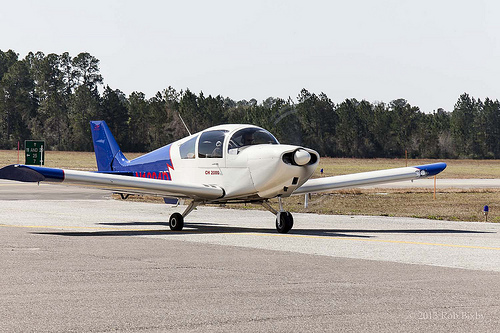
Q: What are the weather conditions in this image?
A: It is cloudy.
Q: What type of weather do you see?
A: It is cloudy.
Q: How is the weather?
A: It is cloudy.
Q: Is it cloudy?
A: Yes, it is cloudy.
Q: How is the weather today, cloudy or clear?
A: It is cloudy.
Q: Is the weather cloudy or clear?
A: It is cloudy.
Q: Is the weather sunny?
A: No, it is cloudy.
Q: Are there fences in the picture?
A: No, there are no fences.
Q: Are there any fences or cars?
A: No, there are no fences or cars.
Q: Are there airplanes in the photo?
A: Yes, there is an airplane.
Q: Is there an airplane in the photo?
A: Yes, there is an airplane.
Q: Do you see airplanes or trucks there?
A: Yes, there is an airplane.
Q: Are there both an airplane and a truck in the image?
A: No, there is an airplane but no trucks.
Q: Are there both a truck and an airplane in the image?
A: No, there is an airplane but no trucks.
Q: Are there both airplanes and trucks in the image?
A: No, there is an airplane but no trucks.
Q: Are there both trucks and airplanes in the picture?
A: No, there is an airplane but no trucks.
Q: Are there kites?
A: No, there are no kites.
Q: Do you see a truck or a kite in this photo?
A: No, there are no kites or trucks.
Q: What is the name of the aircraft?
A: The aircraft is an airplane.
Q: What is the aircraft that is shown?
A: The aircraft is an airplane.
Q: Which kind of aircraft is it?
A: The aircraft is an airplane.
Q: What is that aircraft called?
A: That is an airplane.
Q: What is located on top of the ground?
A: The airplane is on top of the ground.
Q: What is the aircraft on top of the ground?
A: The aircraft is an airplane.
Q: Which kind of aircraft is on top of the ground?
A: The aircraft is an airplane.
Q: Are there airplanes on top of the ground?
A: Yes, there is an airplane on top of the ground.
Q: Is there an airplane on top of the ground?
A: Yes, there is an airplane on top of the ground.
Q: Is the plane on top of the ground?
A: Yes, the plane is on top of the ground.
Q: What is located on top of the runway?
A: The plane is on top of the runway.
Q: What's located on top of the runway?
A: The plane is on top of the runway.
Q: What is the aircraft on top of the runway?
A: The aircraft is an airplane.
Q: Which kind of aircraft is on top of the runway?
A: The aircraft is an airplane.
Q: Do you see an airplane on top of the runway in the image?
A: Yes, there is an airplane on top of the runway.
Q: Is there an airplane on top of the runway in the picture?
A: Yes, there is an airplane on top of the runway.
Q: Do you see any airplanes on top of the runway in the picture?
A: Yes, there is an airplane on top of the runway.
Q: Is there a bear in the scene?
A: No, there are no bears.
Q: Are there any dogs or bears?
A: No, there are no bears or dogs.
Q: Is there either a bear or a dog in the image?
A: No, there are no bears or dogs.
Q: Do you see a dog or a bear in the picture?
A: No, there are no bears or dogs.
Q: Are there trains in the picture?
A: No, there are no trains.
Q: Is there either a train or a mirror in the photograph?
A: No, there are no trains or mirrors.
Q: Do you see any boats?
A: No, there are no boats.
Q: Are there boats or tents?
A: No, there are no boats or tents.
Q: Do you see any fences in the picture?
A: No, there are no fences.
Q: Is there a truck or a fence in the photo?
A: No, there are no fences or trucks.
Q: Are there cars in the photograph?
A: No, there are no cars.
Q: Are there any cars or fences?
A: No, there are no cars or fences.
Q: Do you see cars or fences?
A: No, there are no cars or fences.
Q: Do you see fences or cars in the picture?
A: No, there are no cars or fences.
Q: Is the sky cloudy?
A: Yes, the sky is cloudy.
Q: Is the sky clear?
A: No, the sky is cloudy.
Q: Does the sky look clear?
A: No, the sky is cloudy.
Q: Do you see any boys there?
A: No, there are no boys.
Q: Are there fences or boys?
A: No, there are no boys or fences.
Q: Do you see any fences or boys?
A: No, there are no boys or fences.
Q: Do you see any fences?
A: No, there are no fences.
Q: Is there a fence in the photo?
A: No, there are no fences.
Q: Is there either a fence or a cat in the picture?
A: No, there are no fences or cats.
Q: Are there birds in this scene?
A: No, there are no birds.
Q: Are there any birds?
A: No, there are no birds.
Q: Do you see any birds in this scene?
A: No, there are no birds.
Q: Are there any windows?
A: Yes, there is a window.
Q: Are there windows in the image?
A: Yes, there is a window.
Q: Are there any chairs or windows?
A: Yes, there is a window.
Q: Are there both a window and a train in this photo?
A: No, there is a window but no trains.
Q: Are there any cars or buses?
A: No, there are no cars or buses.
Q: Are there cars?
A: No, there are no cars.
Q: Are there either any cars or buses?
A: No, there are no cars or buses.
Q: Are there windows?
A: Yes, there are windows.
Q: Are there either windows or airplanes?
A: Yes, there are windows.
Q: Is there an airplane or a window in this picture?
A: Yes, there are windows.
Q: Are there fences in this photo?
A: No, there are no fences.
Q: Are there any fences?
A: No, there are no fences.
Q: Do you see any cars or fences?
A: No, there are no fences or cars.